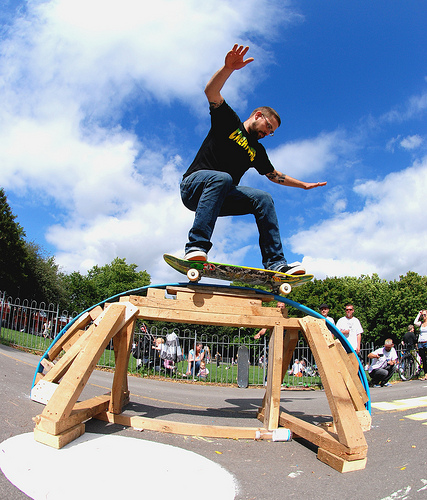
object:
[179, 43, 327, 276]
man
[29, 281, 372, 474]
half-circle